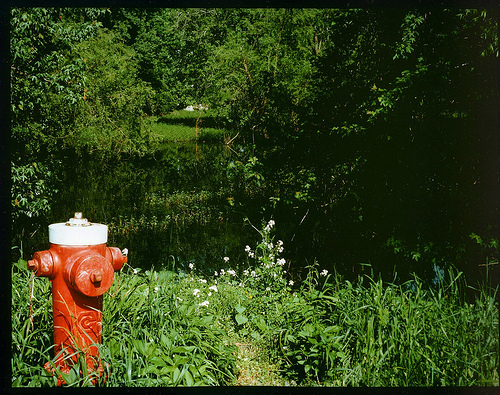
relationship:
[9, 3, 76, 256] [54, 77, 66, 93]
tree has leaf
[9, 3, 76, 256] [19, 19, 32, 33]
tree has leaf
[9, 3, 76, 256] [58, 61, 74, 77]
tree has leaf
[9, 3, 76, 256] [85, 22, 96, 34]
tree has leaf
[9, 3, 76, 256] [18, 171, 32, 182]
tree has leaf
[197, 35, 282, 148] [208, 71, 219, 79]
tree has leaf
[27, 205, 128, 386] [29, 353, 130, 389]
hydrant on grass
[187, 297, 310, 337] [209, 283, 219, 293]
grass has flower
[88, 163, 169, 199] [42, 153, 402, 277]
reflection on water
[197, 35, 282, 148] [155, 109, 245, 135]
tree has shadow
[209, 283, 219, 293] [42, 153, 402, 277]
flower by water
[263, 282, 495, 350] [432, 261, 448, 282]
grass has flower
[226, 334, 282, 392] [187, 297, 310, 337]
trail in grass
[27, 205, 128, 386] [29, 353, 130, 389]
hydrant by grass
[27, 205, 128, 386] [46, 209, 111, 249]
hydrant has top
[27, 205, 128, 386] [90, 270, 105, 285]
hydrant has lug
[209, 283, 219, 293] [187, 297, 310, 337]
flower in grass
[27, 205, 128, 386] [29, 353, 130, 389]
hydrant in grass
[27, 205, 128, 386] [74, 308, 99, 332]
hydrant has letter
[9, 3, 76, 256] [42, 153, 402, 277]
tree by water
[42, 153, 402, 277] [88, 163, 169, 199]
water has reflection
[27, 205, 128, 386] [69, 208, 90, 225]
hydrant has lug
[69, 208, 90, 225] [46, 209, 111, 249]
lug on top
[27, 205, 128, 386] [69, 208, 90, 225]
hydrant has bolt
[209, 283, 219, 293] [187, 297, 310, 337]
flower on grass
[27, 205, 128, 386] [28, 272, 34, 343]
hydrant has chain